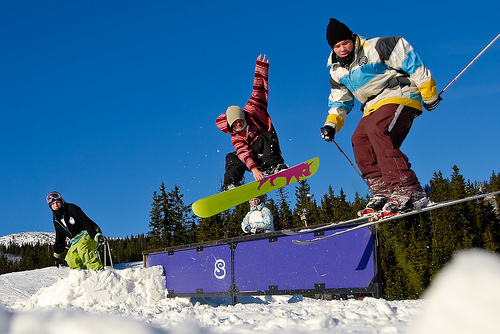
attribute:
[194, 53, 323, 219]
snowboarder — jumping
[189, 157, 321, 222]
snowboard — purple, green, yellow, purples, brightly colored, green with pink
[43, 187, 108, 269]
skier — looking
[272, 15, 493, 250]
skier — jumping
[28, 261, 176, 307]
ramp — big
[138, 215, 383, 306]
fence — blue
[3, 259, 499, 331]
snow — white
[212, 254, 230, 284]
logo — white, blue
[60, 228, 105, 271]
pants — lime green, maroon, green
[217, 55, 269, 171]
shirt — red, pink, purple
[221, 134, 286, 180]
pants — black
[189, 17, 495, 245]
skiers — in air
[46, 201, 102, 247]
coat — black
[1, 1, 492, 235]
sky — blue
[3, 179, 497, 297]
trees — green, pine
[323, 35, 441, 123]
jacket — striped, gray,blue,, white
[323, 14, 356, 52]
cap — black